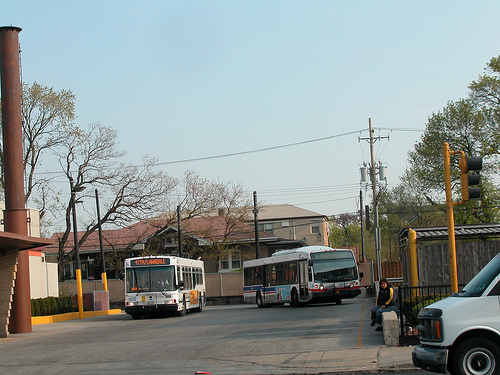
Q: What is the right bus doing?
A: Turning.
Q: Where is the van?
A: Street on right.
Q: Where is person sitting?
A: Ledge.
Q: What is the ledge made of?
A: Concrete.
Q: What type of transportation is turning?
A: Bus.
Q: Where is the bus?
A: Street.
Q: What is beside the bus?
A: Fence.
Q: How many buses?
A: Two.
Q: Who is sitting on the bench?
A: A person in black top.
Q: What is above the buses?
A: Power line.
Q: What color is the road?
A: Grey.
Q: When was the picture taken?
A: During daytime.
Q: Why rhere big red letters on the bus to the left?
A: To indicate the destination.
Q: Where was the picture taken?
A: In a city.